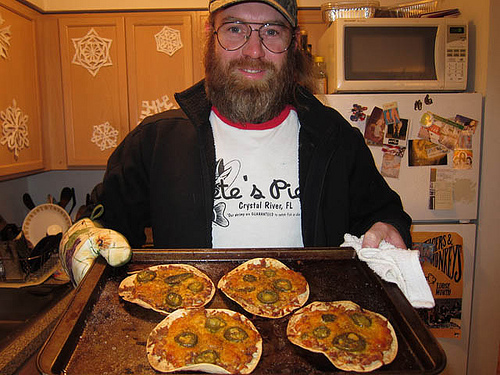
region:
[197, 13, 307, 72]
glasses on man's head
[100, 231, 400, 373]
food on the pan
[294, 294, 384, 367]
toppings on the food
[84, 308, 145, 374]
pan under the food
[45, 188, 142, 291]
oven mit on hand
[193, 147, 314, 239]
words on the shirt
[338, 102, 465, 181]
fridge in the background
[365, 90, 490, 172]
items on the fridge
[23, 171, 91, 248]
plate in the background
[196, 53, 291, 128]
beard on man's face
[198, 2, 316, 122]
head of a person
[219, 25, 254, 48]
eye of a person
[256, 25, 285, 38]
eye of a person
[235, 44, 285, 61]
nose of a person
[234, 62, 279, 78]
mouth of a person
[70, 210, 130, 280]
hand of a person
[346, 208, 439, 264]
hand of a person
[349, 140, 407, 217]
arm of a person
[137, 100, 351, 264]
body of a person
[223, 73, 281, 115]
beard of a person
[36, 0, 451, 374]
Man wearing glasses cooking food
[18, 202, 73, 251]
Plate with gold colored trim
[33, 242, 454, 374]
Food on a cookie sheet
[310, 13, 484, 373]
Microwave oven on top of refrigerator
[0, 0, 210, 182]
White snowflake cutouts on cupboards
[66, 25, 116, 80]
White snowflake decoration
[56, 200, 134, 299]
White with green potholder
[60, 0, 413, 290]
Man wearing eye glasses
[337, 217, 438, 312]
Person's hand holding small white towel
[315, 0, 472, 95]
White microwave oven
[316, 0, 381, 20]
a grey foil food tray.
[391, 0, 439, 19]
a clear plastic food top.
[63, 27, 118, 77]
a white decoration star .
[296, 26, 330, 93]
bottles sitting on top the refrigerator.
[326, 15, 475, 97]
a small white microwave.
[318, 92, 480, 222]
a white refrigerator freezer.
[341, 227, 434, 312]
a white kitchen towel.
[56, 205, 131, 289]
a green orange and brown glove.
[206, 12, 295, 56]
a man is wearing a pair of clear glasses.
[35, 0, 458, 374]
a man is holding a tray with pizza tortillas.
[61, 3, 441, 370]
A man holding a plate of four small pizzas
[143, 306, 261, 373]
A pizza with jalapenos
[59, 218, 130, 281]
A yellow oven mitt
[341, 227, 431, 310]
A white kitchen towel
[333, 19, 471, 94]
A white microwave on top of a refrigerator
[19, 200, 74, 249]
A white and gold dish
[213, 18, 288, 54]
Glasses on a man's face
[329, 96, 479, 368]
A refrigerator covered in magnets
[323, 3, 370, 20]
A clear plastic food container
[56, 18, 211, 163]
Lacey decorations on brown kitchen cabinets